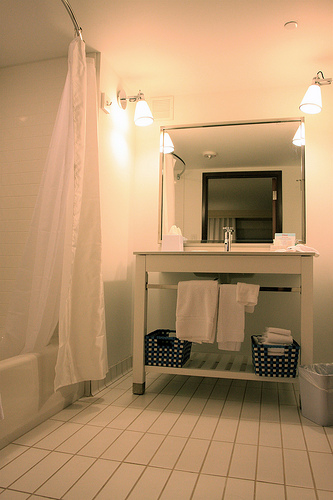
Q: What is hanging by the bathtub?
A: A shower curtain.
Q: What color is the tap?
A: Silver.